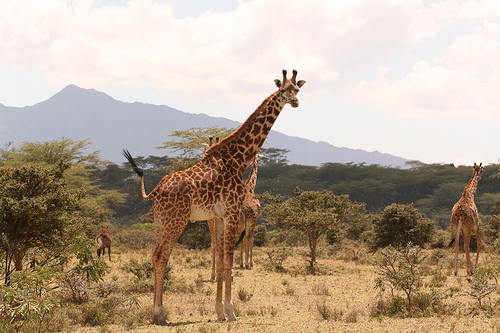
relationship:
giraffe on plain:
[120, 69, 308, 322] [1, 242, 499, 333]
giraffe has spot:
[120, 69, 308, 322] [252, 124, 263, 136]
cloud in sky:
[7, 0, 500, 164] [1, 0, 500, 165]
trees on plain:
[2, 128, 500, 271] [1, 242, 499, 333]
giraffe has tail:
[120, 69, 308, 322] [122, 149, 153, 202]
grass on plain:
[2, 247, 500, 332] [1, 242, 499, 333]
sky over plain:
[1, 0, 500, 165] [1, 242, 499, 333]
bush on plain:
[361, 204, 450, 321] [1, 242, 499, 333]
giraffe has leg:
[120, 69, 308, 322] [153, 223, 187, 325]